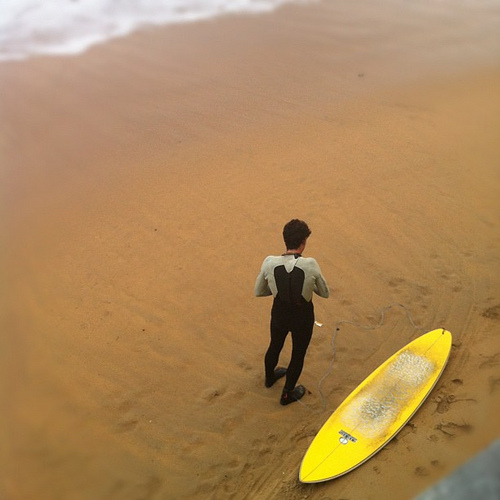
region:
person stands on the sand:
[233, 207, 340, 411]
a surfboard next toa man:
[288, 317, 465, 489]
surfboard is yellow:
[274, 317, 497, 488]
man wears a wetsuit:
[238, 203, 345, 412]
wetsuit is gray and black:
[247, 253, 337, 395]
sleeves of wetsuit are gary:
[247, 248, 334, 310]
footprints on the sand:
[418, 381, 486, 463]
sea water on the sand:
[6, 0, 296, 67]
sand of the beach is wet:
[0, 53, 483, 459]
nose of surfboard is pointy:
[279, 428, 362, 490]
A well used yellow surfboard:
[291, 311, 465, 491]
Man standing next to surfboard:
[233, 203, 472, 499]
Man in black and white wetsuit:
[246, 213, 333, 419]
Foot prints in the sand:
[196, 370, 491, 463]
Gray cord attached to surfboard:
[321, 306, 458, 410]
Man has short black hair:
[280, 218, 318, 254]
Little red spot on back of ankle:
[278, 389, 291, 406]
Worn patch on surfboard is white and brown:
[321, 346, 435, 441]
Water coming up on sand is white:
[6, 3, 275, 53]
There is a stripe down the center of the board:
[305, 321, 454, 495]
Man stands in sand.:
[242, 215, 333, 410]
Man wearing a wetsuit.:
[244, 249, 335, 406]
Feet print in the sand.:
[431, 386, 468, 475]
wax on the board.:
[342, 341, 436, 444]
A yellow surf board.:
[296, 306, 488, 499]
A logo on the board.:
[334, 426, 360, 452]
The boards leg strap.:
[336, 291, 445, 340]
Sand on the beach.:
[285, 96, 426, 192]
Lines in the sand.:
[264, 451, 302, 499]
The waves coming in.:
[26, 9, 259, 89]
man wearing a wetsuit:
[250, 211, 343, 388]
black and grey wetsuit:
[262, 246, 326, 423]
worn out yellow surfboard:
[325, 317, 455, 476]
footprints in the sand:
[197, 424, 287, 499]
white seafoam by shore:
[33, 7, 127, 52]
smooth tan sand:
[81, 60, 243, 154]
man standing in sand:
[256, 213, 326, 403]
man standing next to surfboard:
[247, 227, 442, 489]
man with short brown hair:
[263, 214, 315, 417]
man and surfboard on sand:
[264, 211, 449, 475]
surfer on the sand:
[237, 200, 340, 407]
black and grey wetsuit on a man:
[252, 252, 329, 403]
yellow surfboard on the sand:
[297, 308, 467, 488]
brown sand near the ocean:
[37, 152, 208, 426]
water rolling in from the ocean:
[4, 3, 273, 65]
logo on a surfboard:
[333, 427, 360, 448]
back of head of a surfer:
[271, 206, 318, 256]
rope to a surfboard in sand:
[314, 295, 451, 364]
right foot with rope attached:
[277, 380, 310, 409]